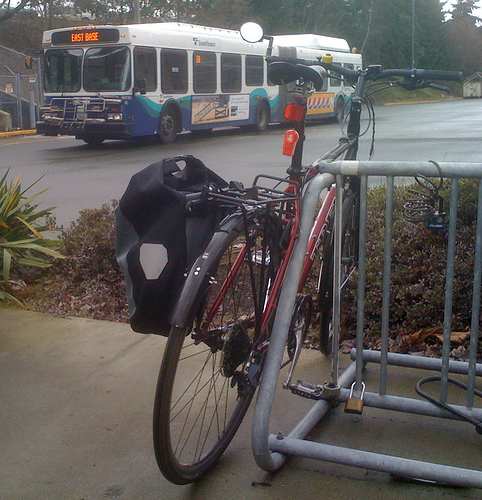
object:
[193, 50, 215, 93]
window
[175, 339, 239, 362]
spoke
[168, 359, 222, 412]
spoke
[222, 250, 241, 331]
spoke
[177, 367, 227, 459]
spoke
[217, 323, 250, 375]
gears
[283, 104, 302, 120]
reflector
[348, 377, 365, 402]
paddle lock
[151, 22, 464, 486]
bicycle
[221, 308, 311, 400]
chain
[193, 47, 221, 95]
windows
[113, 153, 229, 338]
back pack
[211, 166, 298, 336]
wheel rack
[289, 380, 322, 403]
pedal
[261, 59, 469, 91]
bike handle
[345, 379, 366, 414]
lock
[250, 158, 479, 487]
bars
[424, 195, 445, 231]
lock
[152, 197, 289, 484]
rear wheel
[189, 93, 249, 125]
billboard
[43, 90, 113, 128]
bikerack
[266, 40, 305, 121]
extender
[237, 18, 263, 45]
bicycle mirror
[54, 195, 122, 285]
shrubs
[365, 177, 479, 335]
shrubs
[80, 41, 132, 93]
window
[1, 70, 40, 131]
fence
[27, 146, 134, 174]
paved area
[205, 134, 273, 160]
paved area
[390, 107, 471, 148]
paved area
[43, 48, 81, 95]
windshield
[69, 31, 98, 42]
bus sign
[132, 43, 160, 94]
windows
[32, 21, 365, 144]
bus